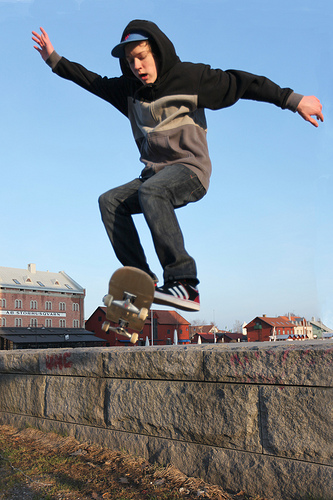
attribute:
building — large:
[0, 264, 97, 344]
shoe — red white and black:
[136, 254, 218, 330]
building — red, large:
[243, 313, 295, 342]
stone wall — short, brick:
[1, 356, 330, 480]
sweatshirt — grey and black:
[41, 18, 305, 193]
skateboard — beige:
[103, 265, 154, 343]